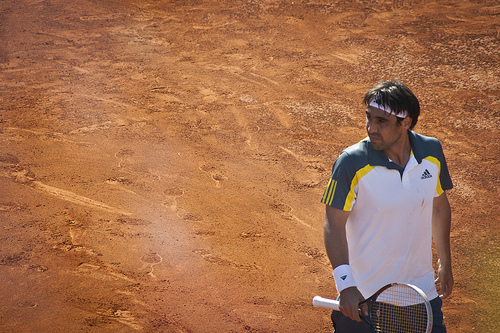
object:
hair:
[359, 81, 418, 129]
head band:
[361, 90, 409, 115]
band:
[331, 262, 357, 292]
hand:
[336, 282, 368, 322]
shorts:
[328, 288, 448, 331]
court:
[1, 0, 497, 330]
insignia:
[418, 171, 433, 179]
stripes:
[318, 176, 338, 208]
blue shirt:
[318, 130, 454, 305]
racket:
[310, 282, 434, 332]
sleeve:
[320, 151, 354, 210]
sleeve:
[435, 133, 452, 198]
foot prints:
[200, 247, 258, 272]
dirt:
[161, 183, 186, 198]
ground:
[1, 0, 498, 330]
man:
[319, 81, 454, 331]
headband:
[365, 93, 407, 118]